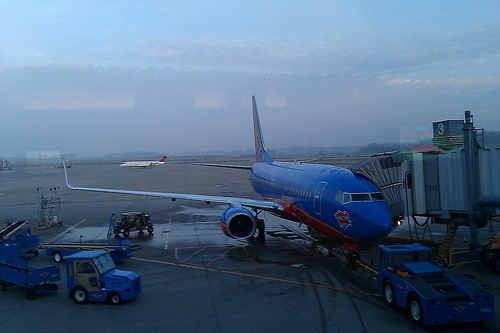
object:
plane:
[63, 96, 392, 264]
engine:
[221, 207, 257, 240]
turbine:
[229, 214, 253, 237]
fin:
[251, 95, 272, 162]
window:
[351, 194, 370, 201]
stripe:
[263, 196, 353, 240]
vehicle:
[0, 250, 140, 305]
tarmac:
[0, 163, 499, 330]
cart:
[377, 245, 494, 329]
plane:
[120, 155, 168, 167]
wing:
[61, 160, 284, 212]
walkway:
[354, 145, 499, 214]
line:
[132, 257, 379, 297]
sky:
[0, 0, 500, 160]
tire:
[71, 288, 89, 304]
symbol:
[334, 209, 352, 230]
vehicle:
[114, 211, 154, 236]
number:
[437, 123, 444, 135]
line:
[305, 269, 327, 333]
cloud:
[67, 52, 486, 85]